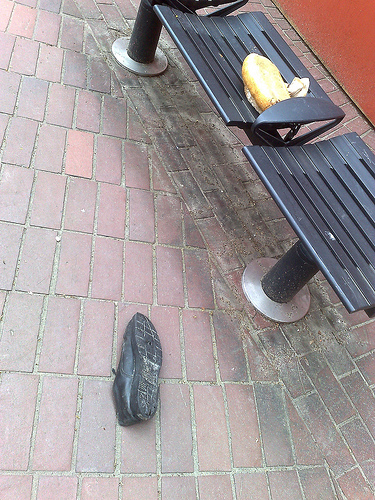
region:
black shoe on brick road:
[113, 299, 198, 431]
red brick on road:
[196, 393, 237, 469]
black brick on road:
[253, 383, 290, 428]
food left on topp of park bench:
[241, 22, 309, 111]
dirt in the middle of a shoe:
[139, 355, 151, 381]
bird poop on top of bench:
[315, 224, 347, 244]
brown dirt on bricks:
[187, 111, 259, 196]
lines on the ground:
[29, 159, 153, 249]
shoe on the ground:
[76, 307, 196, 433]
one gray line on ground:
[168, 392, 214, 455]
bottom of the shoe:
[126, 332, 168, 407]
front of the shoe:
[104, 298, 176, 343]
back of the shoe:
[119, 388, 179, 429]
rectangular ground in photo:
[12, 176, 133, 301]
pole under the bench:
[257, 236, 325, 311]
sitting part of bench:
[287, 148, 372, 247]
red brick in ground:
[0, 364, 35, 472]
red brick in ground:
[79, 377, 123, 475]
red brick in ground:
[121, 419, 156, 472]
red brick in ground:
[158, 377, 194, 472]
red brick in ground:
[187, 378, 233, 471]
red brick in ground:
[222, 377, 264, 473]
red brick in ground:
[250, 373, 292, 467]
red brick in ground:
[282, 389, 328, 470]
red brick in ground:
[93, 235, 121, 300]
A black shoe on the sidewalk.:
[122, 308, 173, 454]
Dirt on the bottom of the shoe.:
[135, 317, 151, 398]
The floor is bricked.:
[32, 233, 165, 306]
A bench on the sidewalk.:
[252, 142, 358, 282]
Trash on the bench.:
[230, 42, 295, 115]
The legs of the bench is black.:
[257, 260, 309, 302]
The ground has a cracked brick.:
[96, 6, 138, 42]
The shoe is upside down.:
[100, 309, 167, 427]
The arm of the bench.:
[252, 84, 351, 135]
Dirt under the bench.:
[221, 271, 336, 371]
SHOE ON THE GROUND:
[108, 306, 167, 428]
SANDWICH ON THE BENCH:
[235, 48, 313, 114]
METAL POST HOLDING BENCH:
[236, 231, 328, 322]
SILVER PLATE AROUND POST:
[239, 252, 314, 326]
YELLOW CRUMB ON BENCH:
[174, 12, 180, 20]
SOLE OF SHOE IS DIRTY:
[131, 308, 164, 413]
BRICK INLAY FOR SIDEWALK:
[11, 45, 99, 192]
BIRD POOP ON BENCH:
[322, 227, 338, 245]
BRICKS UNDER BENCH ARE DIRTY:
[159, 76, 252, 252]